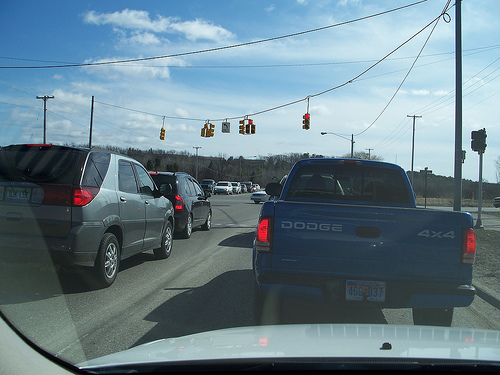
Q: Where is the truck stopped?
A: At a red light.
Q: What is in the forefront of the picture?
A: A white car hood.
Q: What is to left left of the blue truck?
A: A gray SUV.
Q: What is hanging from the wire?
A: Traffic lights.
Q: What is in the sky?
A: Light clouds.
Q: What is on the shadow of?
A: Blue truck.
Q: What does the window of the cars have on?
A: Tintes.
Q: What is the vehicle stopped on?
A: Traffic light.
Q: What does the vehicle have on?
A: Brake lights.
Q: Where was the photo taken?
A: On the highway.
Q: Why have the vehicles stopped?
A: The traffic lights are red for stop.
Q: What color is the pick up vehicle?
A: Blue.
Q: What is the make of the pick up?
A: Dodge.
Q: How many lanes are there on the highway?
A: 2.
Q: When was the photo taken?
A: Day time.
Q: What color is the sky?
A: Blue.